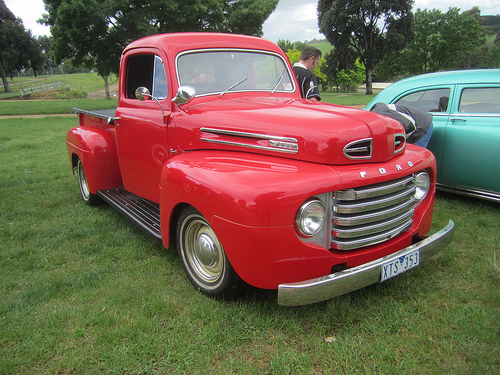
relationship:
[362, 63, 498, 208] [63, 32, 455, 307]
car next to pickup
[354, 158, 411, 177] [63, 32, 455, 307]
ford sign on pickup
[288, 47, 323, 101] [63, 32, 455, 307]
man standing next to pickup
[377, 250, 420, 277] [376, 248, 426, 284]
letters on plate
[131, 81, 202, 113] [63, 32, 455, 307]
double mirrors are on pickup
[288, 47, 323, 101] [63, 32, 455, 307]
man leaning on pickup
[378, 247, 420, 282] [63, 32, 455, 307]
plate on pickup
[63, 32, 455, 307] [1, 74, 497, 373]
pickup on grass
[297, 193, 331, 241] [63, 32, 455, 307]
headlight on pickup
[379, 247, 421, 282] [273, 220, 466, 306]
license plate on bumper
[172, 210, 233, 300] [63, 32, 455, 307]
tire on pickup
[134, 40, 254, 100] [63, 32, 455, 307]
windshield on pickup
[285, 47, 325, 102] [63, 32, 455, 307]
man standing by pickup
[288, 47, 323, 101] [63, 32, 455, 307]
man next to pickup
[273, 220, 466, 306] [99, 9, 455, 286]
bumper on truck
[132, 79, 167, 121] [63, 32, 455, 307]
mirror on pickup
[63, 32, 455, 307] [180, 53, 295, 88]
pickup has windshield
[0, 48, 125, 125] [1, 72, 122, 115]
road on background